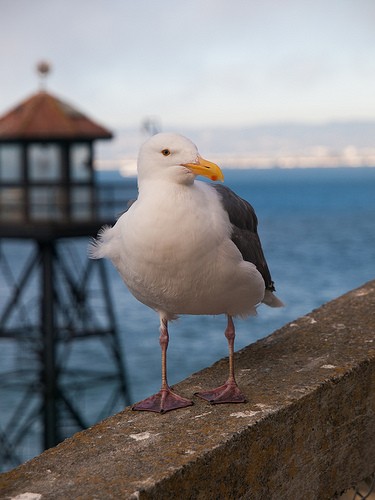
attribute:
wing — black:
[216, 182, 277, 290]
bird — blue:
[105, 132, 277, 414]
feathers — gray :
[214, 182, 278, 295]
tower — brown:
[2, 57, 135, 484]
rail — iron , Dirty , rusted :
[3, 282, 372, 498]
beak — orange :
[183, 158, 223, 182]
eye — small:
[161, 146, 178, 158]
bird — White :
[83, 132, 278, 415]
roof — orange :
[3, 86, 93, 142]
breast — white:
[146, 219, 221, 300]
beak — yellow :
[178, 154, 226, 185]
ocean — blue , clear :
[0, 164, 372, 353]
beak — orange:
[181, 156, 224, 182]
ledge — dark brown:
[1, 279, 373, 498]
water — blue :
[248, 167, 363, 257]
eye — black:
[158, 147, 171, 155]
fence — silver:
[335, 480, 373, 498]